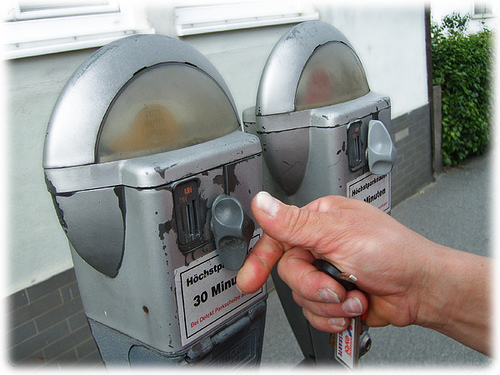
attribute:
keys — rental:
[310, 254, 361, 366]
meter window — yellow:
[92, 59, 241, 161]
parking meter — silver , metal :
[56, 108, 258, 328]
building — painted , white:
[13, 22, 452, 235]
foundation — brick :
[11, 273, 93, 360]